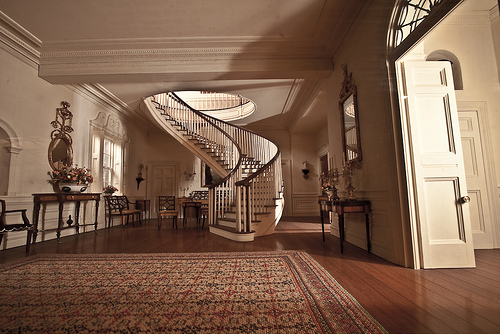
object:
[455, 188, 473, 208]
knob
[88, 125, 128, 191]
window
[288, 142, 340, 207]
sconce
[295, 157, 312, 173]
candle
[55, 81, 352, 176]
decorative mirror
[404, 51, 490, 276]
door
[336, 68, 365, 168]
mirror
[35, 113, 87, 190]
mirror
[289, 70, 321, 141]
ground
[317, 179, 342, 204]
canelabra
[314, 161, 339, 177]
candles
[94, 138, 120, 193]
window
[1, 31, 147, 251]
wall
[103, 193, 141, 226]
bench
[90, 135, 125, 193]
window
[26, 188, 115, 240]
table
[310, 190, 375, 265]
table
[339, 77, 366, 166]
mirror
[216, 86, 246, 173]
wall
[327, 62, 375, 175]
mirror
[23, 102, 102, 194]
mirror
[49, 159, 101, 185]
flowers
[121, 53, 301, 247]
staircase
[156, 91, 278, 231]
staircase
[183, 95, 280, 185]
bannister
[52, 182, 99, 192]
bowl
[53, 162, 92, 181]
flowers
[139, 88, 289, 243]
stairway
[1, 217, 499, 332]
floor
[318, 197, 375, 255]
table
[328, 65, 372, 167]
mirror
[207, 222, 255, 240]
step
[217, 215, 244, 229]
step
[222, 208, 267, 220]
step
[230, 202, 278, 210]
step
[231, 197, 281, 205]
step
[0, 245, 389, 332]
rug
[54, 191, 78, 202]
wood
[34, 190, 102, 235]
table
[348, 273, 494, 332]
floor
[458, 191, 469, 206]
handle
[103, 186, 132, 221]
bench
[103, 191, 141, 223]
chairs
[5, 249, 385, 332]
persian rug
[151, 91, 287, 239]
white staircase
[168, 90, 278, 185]
dark railing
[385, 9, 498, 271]
doorway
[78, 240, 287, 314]
rug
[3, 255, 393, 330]
rug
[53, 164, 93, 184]
potted flowers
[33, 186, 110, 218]
table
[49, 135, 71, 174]
mirror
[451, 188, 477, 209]
door knob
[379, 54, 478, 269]
painted door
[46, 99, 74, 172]
frame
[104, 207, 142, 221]
upholstery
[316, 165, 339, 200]
candleabra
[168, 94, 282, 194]
trim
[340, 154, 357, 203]
candelabra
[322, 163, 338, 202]
candelabra